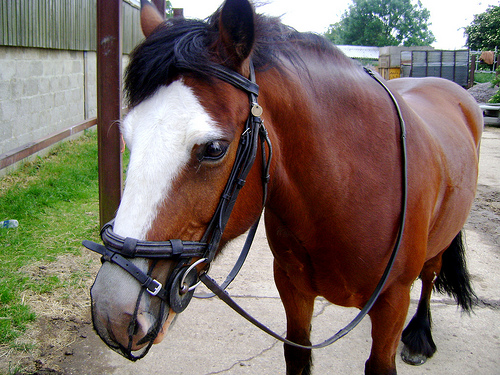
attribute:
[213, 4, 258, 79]
ear — brown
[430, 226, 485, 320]
tail — black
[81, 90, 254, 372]
face — white, horse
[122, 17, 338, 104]
mane — black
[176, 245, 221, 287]
bridle ring — silver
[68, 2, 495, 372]
horse — brown, saddled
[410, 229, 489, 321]
tail — horse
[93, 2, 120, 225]
red pole — metallic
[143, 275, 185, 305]
buckle — silver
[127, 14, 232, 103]
mane — black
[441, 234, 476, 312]
tail — blackish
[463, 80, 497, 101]
dirt — pile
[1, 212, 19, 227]
bottle — clear, plastic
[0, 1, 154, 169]
wall — concrete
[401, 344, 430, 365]
hoof — black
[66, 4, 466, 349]
horse — v